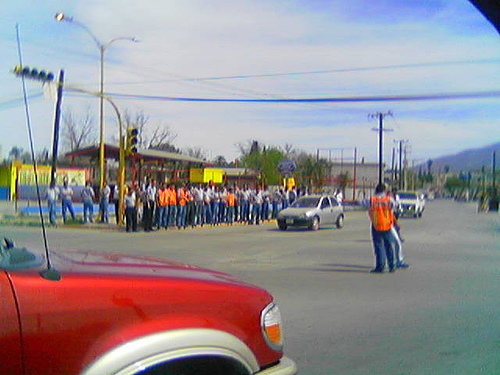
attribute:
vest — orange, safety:
[367, 193, 395, 232]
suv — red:
[2, 233, 300, 375]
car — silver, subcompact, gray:
[276, 190, 346, 230]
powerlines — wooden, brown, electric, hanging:
[283, 113, 423, 195]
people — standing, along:
[117, 182, 300, 234]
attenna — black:
[14, 21, 60, 279]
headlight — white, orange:
[52, 12, 67, 25]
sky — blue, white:
[4, 4, 498, 182]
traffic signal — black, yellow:
[14, 67, 138, 229]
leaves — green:
[220, 140, 499, 193]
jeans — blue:
[373, 226, 396, 277]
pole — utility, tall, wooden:
[377, 108, 387, 197]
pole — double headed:
[51, 10, 142, 229]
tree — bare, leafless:
[52, 97, 181, 166]